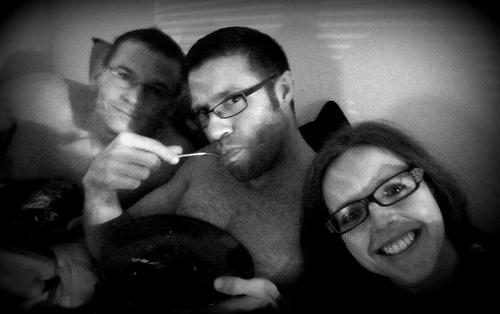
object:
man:
[82, 26, 320, 314]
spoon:
[175, 151, 219, 159]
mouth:
[213, 144, 245, 161]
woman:
[300, 121, 498, 313]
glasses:
[325, 160, 427, 235]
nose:
[367, 200, 398, 232]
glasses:
[186, 72, 280, 131]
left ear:
[277, 70, 294, 106]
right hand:
[81, 131, 185, 190]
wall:
[0, 0, 495, 234]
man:
[1, 26, 197, 250]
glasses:
[109, 64, 173, 101]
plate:
[95, 214, 255, 312]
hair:
[299, 119, 471, 300]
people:
[0, 25, 500, 314]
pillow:
[68, 32, 364, 145]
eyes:
[381, 181, 408, 199]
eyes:
[218, 91, 246, 111]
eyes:
[114, 69, 137, 84]